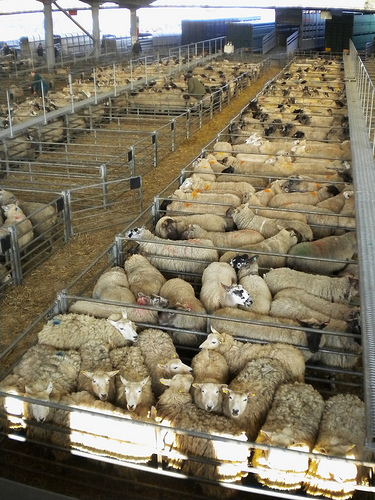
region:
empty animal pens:
[40, 113, 193, 180]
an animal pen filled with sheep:
[82, 238, 364, 356]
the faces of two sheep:
[195, 381, 251, 418]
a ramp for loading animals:
[253, 27, 307, 59]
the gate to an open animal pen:
[56, 174, 156, 235]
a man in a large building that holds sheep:
[30, 37, 49, 61]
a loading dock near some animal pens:
[174, 5, 373, 60]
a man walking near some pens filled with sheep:
[118, 31, 159, 70]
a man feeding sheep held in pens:
[172, 67, 220, 106]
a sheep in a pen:
[123, 222, 217, 273]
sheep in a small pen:
[124, 223, 219, 271]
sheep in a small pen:
[199, 323, 306, 389]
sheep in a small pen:
[189, 347, 230, 414]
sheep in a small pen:
[218, 347, 290, 433]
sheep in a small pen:
[101, 345, 162, 410]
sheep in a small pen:
[219, 221, 306, 267]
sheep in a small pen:
[0, 198, 35, 254]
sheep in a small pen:
[19, 343, 83, 423]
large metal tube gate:
[65, 170, 145, 239]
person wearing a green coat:
[182, 69, 208, 102]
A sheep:
[222, 379, 250, 442]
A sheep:
[226, 390, 245, 431]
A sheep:
[207, 341, 244, 441]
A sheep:
[233, 392, 249, 441]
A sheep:
[219, 363, 249, 426]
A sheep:
[225, 392, 242, 472]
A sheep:
[210, 373, 242, 428]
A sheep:
[232, 332, 281, 442]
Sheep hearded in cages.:
[253, 43, 353, 486]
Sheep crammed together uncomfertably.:
[54, 244, 366, 473]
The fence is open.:
[68, 173, 147, 233]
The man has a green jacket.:
[181, 66, 209, 102]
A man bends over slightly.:
[185, 73, 206, 102]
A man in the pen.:
[173, 70, 212, 101]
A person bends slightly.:
[28, 66, 55, 96]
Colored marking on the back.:
[284, 235, 339, 265]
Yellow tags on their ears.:
[159, 375, 265, 407]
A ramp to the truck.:
[262, 29, 296, 60]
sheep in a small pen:
[121, 247, 167, 303]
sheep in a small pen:
[92, 259, 134, 310]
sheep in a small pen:
[196, 257, 253, 313]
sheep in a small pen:
[71, 335, 121, 403]